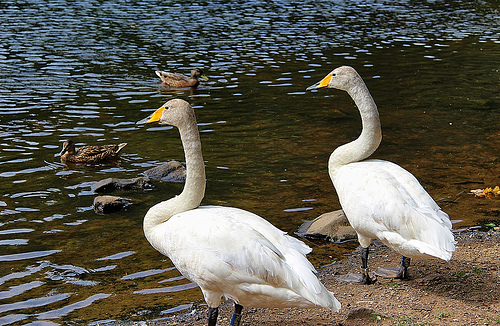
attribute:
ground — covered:
[296, 238, 499, 324]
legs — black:
[185, 299, 257, 324]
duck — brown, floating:
[39, 126, 137, 168]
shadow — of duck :
[394, 260, 490, 308]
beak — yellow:
[135, 107, 165, 123]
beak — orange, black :
[123, 103, 171, 134]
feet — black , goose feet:
[334, 242, 418, 282]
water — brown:
[215, 101, 297, 166]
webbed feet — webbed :
[322, 245, 397, 288]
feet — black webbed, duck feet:
[340, 251, 412, 284]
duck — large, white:
[305, 65, 457, 284]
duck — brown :
[152, 66, 211, 94]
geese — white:
[103, 62, 469, 324]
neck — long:
[163, 128, 213, 195]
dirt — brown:
[332, 273, 392, 323]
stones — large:
[36, 16, 107, 119]